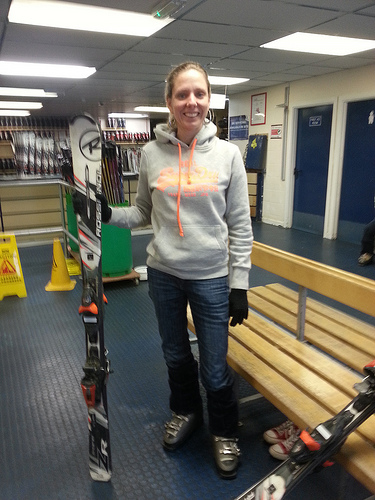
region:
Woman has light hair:
[157, 54, 217, 102]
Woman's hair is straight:
[148, 50, 217, 98]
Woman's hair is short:
[157, 55, 219, 106]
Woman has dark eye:
[174, 92, 190, 100]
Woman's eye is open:
[178, 88, 187, 99]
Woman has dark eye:
[193, 85, 204, 101]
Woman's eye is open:
[194, 88, 212, 103]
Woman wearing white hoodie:
[114, 117, 262, 286]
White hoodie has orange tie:
[165, 135, 204, 250]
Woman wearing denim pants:
[144, 256, 250, 439]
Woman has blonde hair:
[162, 60, 212, 69]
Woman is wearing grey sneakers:
[160, 402, 241, 466]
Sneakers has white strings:
[162, 416, 184, 431]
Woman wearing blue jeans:
[147, 274, 224, 345]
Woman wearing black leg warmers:
[161, 362, 237, 414]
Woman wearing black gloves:
[229, 284, 252, 333]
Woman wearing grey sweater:
[148, 145, 244, 274]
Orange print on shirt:
[147, 139, 222, 237]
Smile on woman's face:
[162, 52, 218, 140]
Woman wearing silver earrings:
[206, 105, 220, 131]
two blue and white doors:
[282, 93, 372, 240]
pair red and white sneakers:
[260, 421, 305, 464]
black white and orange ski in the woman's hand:
[67, 110, 110, 485]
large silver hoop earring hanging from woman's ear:
[201, 107, 215, 123]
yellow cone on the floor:
[35, 236, 78, 292]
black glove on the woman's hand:
[230, 287, 252, 329]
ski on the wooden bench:
[236, 348, 372, 499]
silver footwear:
[157, 405, 245, 476]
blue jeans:
[148, 267, 230, 382]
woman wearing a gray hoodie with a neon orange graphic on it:
[111, 62, 252, 287]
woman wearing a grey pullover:
[112, 54, 250, 289]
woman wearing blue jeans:
[142, 260, 239, 426]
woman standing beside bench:
[105, 55, 370, 403]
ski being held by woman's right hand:
[68, 61, 204, 483]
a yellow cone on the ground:
[39, 233, 80, 302]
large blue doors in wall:
[285, 93, 373, 247]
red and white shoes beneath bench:
[243, 324, 363, 461]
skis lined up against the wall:
[10, 127, 70, 181]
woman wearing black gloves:
[97, 184, 259, 327]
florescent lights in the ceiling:
[0, 1, 372, 120]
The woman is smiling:
[136, 60, 233, 159]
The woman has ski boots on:
[142, 405, 234, 490]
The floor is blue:
[12, 391, 165, 499]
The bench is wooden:
[255, 266, 369, 431]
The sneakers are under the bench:
[262, 416, 355, 499]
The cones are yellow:
[38, 221, 88, 298]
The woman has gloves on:
[211, 259, 287, 382]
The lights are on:
[6, 10, 120, 121]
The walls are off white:
[303, 80, 365, 118]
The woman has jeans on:
[126, 255, 271, 428]